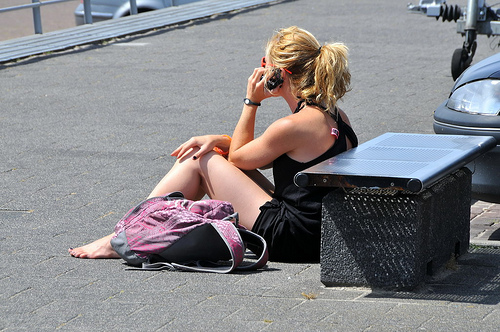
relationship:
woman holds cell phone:
[68, 25, 353, 271] [261, 66, 285, 89]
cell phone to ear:
[261, 66, 285, 89] [273, 59, 301, 88]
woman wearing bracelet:
[68, 25, 353, 271] [235, 87, 250, 116]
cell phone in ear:
[260, 68, 285, 91] [267, 64, 289, 86]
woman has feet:
[68, 25, 353, 271] [68, 224, 161, 276]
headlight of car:
[442, 77, 484, 114] [433, 80, 494, 132]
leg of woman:
[123, 144, 263, 229] [68, 25, 353, 271]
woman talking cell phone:
[68, 25, 353, 271] [262, 70, 287, 93]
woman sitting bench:
[68, 25, 359, 262] [299, 129, 494, 279]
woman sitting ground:
[68, 25, 359, 262] [5, 4, 484, 316]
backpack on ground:
[101, 167, 268, 273] [5, 4, 484, 316]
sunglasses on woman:
[257, 52, 296, 81] [68, 25, 353, 271]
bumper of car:
[432, 107, 499, 149] [431, 54, 498, 202]